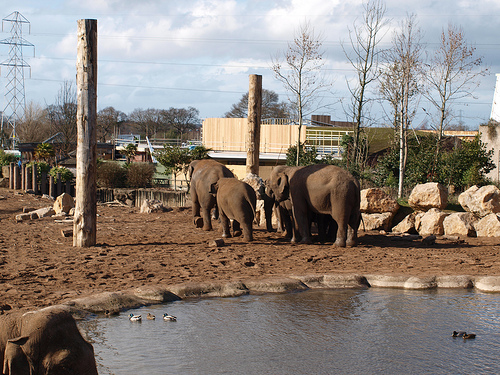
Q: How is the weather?
A: It is cloudy.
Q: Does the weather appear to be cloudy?
A: Yes, it is cloudy.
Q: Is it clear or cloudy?
A: It is cloudy.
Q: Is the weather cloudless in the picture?
A: No, it is cloudy.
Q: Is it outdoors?
A: Yes, it is outdoors.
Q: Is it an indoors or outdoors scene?
A: It is outdoors.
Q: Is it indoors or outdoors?
A: It is outdoors.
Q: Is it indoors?
A: No, it is outdoors.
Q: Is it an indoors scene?
A: No, it is outdoors.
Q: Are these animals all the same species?
A: No, there are both ducks and elephants.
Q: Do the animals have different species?
A: Yes, they are ducks and elephants.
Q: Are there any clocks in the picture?
A: No, there are no clocks.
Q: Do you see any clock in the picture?
A: No, there are no clocks.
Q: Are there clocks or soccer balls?
A: No, there are no clocks or soccer balls.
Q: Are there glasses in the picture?
A: No, there are no glasses.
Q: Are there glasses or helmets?
A: No, there are no glasses or helmets.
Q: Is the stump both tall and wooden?
A: Yes, the stump is tall and wooden.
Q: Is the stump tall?
A: Yes, the stump is tall.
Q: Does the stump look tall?
A: Yes, the stump is tall.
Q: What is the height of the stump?
A: The stump is tall.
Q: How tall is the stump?
A: The stump is tall.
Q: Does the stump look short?
A: No, the stump is tall.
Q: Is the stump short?
A: No, the stump is tall.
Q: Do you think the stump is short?
A: No, the stump is tall.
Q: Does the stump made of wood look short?
A: No, the stump is tall.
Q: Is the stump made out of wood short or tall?
A: The stump is tall.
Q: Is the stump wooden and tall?
A: Yes, the stump is wooden and tall.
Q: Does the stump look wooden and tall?
A: Yes, the stump is wooden and tall.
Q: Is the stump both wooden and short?
A: No, the stump is wooden but tall.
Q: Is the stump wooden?
A: Yes, the stump is wooden.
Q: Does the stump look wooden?
A: Yes, the stump is wooden.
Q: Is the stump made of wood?
A: Yes, the stump is made of wood.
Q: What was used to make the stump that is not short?
A: The stump is made of wood.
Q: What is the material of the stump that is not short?
A: The stump is made of wood.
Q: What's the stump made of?
A: The stump is made of wood.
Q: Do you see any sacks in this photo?
A: No, there are no sacks.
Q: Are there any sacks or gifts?
A: No, there are no sacks or gifts.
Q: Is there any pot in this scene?
A: No, there are no pots.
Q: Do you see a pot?
A: No, there are no pots.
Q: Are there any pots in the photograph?
A: No, there are no pots.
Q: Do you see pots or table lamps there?
A: No, there are no pots or table lamps.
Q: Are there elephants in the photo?
A: Yes, there is an elephant.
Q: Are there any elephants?
A: Yes, there is an elephant.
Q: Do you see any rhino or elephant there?
A: Yes, there is an elephant.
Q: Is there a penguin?
A: No, there are no penguins.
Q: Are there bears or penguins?
A: No, there are no penguins or bears.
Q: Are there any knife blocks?
A: No, there are no knife blocks.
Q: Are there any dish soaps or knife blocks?
A: No, there are no knife blocks or dish soaps.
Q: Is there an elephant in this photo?
A: Yes, there is an elephant.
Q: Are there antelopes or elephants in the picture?
A: Yes, there is an elephant.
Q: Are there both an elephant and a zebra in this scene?
A: No, there is an elephant but no zebras.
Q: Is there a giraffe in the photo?
A: No, there are no giraffes.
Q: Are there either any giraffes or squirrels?
A: No, there are no giraffes or squirrels.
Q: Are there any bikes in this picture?
A: No, there are no bikes.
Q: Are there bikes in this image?
A: No, there are no bikes.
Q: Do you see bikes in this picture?
A: No, there are no bikes.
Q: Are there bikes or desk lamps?
A: No, there are no bikes or desk lamps.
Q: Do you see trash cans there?
A: No, there are no trash cans.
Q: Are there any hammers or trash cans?
A: No, there are no trash cans or hammers.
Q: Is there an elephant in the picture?
A: Yes, there is an elephant.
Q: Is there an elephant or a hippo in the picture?
A: Yes, there is an elephant.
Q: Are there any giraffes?
A: No, there are no giraffes.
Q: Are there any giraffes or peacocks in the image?
A: No, there are no giraffes or peacocks.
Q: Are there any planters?
A: No, there are no planters.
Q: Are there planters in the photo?
A: No, there are no planters.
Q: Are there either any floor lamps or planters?
A: No, there are no planters or floor lamps.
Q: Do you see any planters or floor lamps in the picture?
A: No, there are no planters or floor lamps.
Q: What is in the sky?
A: The clouds are in the sky.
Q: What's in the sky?
A: The clouds are in the sky.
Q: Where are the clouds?
A: The clouds are in the sky.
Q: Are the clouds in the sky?
A: Yes, the clouds are in the sky.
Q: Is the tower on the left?
A: Yes, the tower is on the left of the image.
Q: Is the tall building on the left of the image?
A: Yes, the tower is on the left of the image.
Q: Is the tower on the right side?
A: No, the tower is on the left of the image.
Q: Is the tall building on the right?
A: No, the tower is on the left of the image.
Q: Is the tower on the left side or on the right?
A: The tower is on the left of the image.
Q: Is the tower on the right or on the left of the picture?
A: The tower is on the left of the image.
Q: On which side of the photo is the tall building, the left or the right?
A: The tower is on the left of the image.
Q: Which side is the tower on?
A: The tower is on the left of the image.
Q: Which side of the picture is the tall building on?
A: The tower is on the left of the image.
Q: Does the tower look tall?
A: Yes, the tower is tall.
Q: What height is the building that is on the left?
A: The tower is tall.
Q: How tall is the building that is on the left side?
A: The tower is tall.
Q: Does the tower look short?
A: No, the tower is tall.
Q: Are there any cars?
A: No, there are no cars.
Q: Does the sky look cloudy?
A: Yes, the sky is cloudy.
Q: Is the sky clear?
A: No, the sky is cloudy.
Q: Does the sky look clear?
A: No, the sky is cloudy.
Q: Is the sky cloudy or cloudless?
A: The sky is cloudy.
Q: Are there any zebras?
A: No, there are no zebras.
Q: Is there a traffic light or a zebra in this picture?
A: No, there are no zebras or traffic lights.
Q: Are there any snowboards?
A: No, there are no snowboards.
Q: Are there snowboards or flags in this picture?
A: No, there are no snowboards or flags.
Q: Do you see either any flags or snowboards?
A: No, there are no snowboards or flags.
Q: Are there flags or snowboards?
A: No, there are no snowboards or flags.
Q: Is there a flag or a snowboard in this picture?
A: No, there are no snowboards or flags.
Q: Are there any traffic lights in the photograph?
A: No, there are no traffic lights.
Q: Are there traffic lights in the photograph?
A: No, there are no traffic lights.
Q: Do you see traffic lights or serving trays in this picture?
A: No, there are no traffic lights or serving trays.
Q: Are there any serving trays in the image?
A: No, there are no serving trays.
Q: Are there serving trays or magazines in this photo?
A: No, there are no serving trays or magazines.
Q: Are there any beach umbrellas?
A: No, there are no beach umbrellas.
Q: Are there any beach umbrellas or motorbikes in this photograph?
A: No, there are no beach umbrellas or motorbikes.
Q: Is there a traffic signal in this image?
A: No, there are no traffic lights.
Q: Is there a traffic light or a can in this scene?
A: No, there are no traffic lights or cans.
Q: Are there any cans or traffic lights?
A: No, there are no traffic lights or cans.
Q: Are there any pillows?
A: No, there are no pillows.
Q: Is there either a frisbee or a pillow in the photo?
A: No, there are no pillows or frisbees.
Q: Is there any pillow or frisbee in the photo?
A: No, there are no pillows or frisbees.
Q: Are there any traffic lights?
A: No, there are no traffic lights.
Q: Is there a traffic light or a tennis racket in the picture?
A: No, there are no traffic lights or rackets.